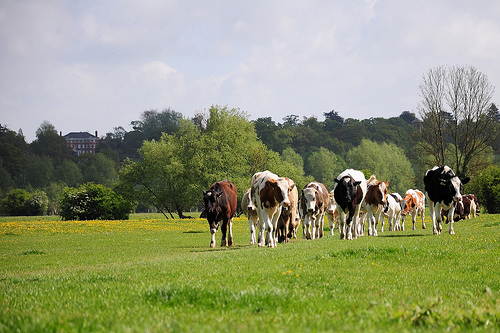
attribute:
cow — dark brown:
[198, 175, 237, 250]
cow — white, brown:
[243, 164, 288, 249]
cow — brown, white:
[236, 185, 261, 247]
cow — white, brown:
[299, 177, 330, 240]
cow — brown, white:
[274, 170, 303, 240]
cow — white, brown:
[360, 172, 391, 236]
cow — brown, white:
[396, 182, 428, 233]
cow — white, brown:
[460, 189, 480, 223]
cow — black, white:
[422, 159, 465, 236]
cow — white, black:
[329, 161, 370, 241]